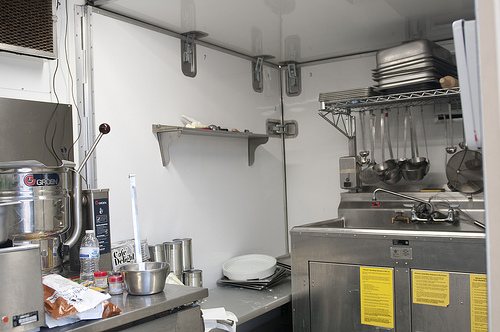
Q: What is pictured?
A: A kitchen prep area.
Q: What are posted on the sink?
A: Yellow signs.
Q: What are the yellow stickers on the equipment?
A: Equipment instructions.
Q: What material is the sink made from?
A: Stainless steel.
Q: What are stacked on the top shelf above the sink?
A: Stainless steel containers.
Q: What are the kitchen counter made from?
A: Stainless steel.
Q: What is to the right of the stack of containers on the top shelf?
A: A rolling pin.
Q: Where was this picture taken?
A: A kitchen.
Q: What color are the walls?
A: White.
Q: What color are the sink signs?
A: Yellow.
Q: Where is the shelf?
A: Hanging on the wall.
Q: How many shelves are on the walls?
A: Two.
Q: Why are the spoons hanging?
A: To dry.